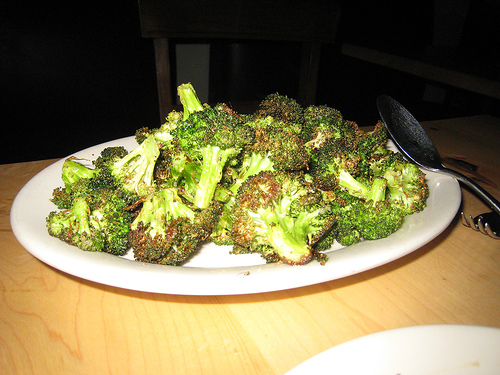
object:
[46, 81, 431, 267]
broccoli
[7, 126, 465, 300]
plate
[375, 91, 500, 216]
utensils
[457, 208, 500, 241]
utensils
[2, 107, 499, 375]
table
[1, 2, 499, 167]
background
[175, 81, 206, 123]
stem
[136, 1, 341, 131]
chair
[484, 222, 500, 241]
tines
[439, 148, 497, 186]
knot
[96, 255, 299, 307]
edge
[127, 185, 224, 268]
piece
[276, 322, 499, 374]
plate